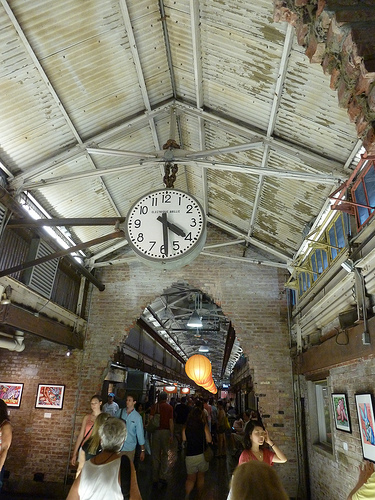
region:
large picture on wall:
[27, 377, 76, 404]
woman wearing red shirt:
[227, 439, 282, 465]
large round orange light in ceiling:
[154, 336, 216, 388]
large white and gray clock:
[123, 173, 213, 273]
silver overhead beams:
[139, 287, 247, 343]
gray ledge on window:
[298, 430, 354, 464]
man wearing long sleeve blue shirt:
[107, 405, 158, 451]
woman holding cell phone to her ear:
[235, 414, 292, 454]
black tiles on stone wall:
[263, 406, 305, 438]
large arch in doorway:
[93, 267, 274, 449]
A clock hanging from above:
[121, 191, 208, 264]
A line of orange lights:
[178, 348, 224, 394]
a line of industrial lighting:
[168, 302, 224, 352]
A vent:
[15, 225, 72, 304]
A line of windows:
[282, 182, 373, 299]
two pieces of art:
[332, 388, 374, 435]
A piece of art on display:
[36, 375, 77, 414]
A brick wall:
[16, 361, 89, 383]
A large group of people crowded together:
[143, 404, 235, 474]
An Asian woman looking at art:
[226, 416, 287, 457]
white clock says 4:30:
[115, 159, 215, 279]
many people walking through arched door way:
[81, 319, 314, 496]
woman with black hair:
[245, 410, 284, 475]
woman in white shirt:
[79, 421, 132, 498]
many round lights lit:
[172, 331, 233, 402]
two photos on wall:
[4, 373, 84, 423]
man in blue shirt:
[118, 394, 146, 465]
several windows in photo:
[278, 161, 373, 268]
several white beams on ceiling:
[32, 139, 372, 291]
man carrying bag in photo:
[147, 394, 182, 470]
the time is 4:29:
[122, 193, 223, 266]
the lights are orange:
[187, 356, 221, 391]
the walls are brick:
[18, 422, 70, 485]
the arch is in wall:
[92, 267, 288, 466]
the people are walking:
[144, 380, 249, 490]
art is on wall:
[1, 376, 78, 426]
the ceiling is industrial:
[161, 296, 237, 401]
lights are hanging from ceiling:
[168, 291, 227, 401]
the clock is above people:
[110, 191, 298, 493]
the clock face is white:
[130, 196, 204, 265]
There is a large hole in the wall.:
[82, 267, 289, 493]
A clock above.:
[99, 167, 221, 281]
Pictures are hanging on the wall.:
[0, 370, 80, 408]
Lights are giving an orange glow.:
[177, 347, 231, 406]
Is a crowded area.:
[74, 363, 287, 498]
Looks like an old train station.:
[21, 144, 372, 493]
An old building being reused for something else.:
[15, 144, 365, 491]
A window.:
[293, 363, 351, 467]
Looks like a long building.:
[138, 349, 251, 451]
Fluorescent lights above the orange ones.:
[178, 304, 232, 413]